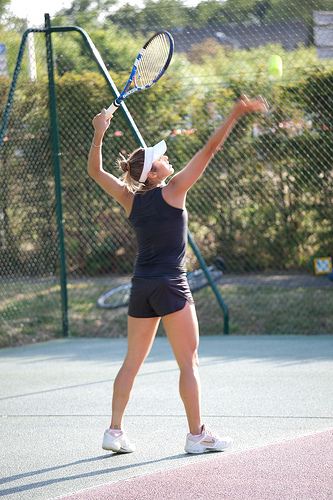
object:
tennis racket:
[100, 29, 175, 116]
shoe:
[185, 423, 231, 454]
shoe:
[103, 428, 136, 452]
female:
[85, 95, 269, 454]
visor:
[139, 139, 167, 185]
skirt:
[126, 270, 188, 319]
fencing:
[0, 0, 331, 336]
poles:
[0, 27, 233, 336]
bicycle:
[100, 258, 226, 302]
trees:
[0, 4, 332, 280]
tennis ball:
[269, 54, 282, 77]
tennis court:
[0, 332, 331, 499]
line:
[43, 412, 331, 493]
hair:
[119, 144, 159, 190]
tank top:
[125, 188, 188, 273]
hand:
[92, 107, 113, 132]